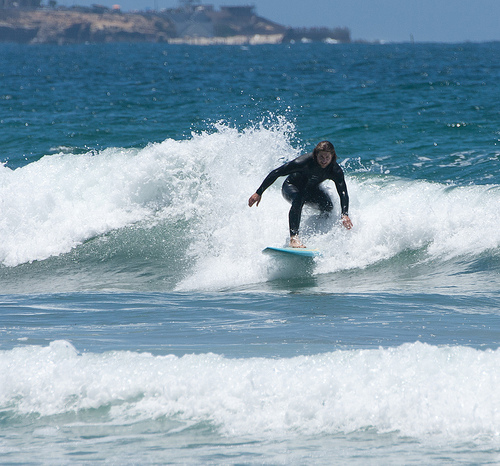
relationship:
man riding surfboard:
[247, 139, 353, 249] [262, 245, 314, 255]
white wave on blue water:
[3, 110, 498, 286] [1, 35, 498, 175]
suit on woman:
[258, 154, 349, 237] [248, 140, 353, 248]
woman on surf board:
[248, 140, 353, 248] [259, 242, 318, 262]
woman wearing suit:
[287, 155, 366, 234] [256, 153, 349, 237]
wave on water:
[205, 127, 268, 176] [45, 270, 465, 362]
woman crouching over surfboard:
[248, 140, 353, 248] [254, 237, 332, 287]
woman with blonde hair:
[248, 140, 353, 248] [307, 137, 337, 157]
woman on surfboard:
[248, 140, 353, 248] [253, 238, 324, 268]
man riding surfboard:
[247, 139, 353, 249] [256, 243, 323, 266]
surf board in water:
[262, 247, 320, 257] [1, 38, 499, 464]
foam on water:
[0, 334, 497, 444] [73, 224, 382, 396]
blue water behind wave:
[346, 56, 442, 108] [46, 149, 238, 293]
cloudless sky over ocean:
[261, 0, 499, 46] [5, 42, 498, 459]